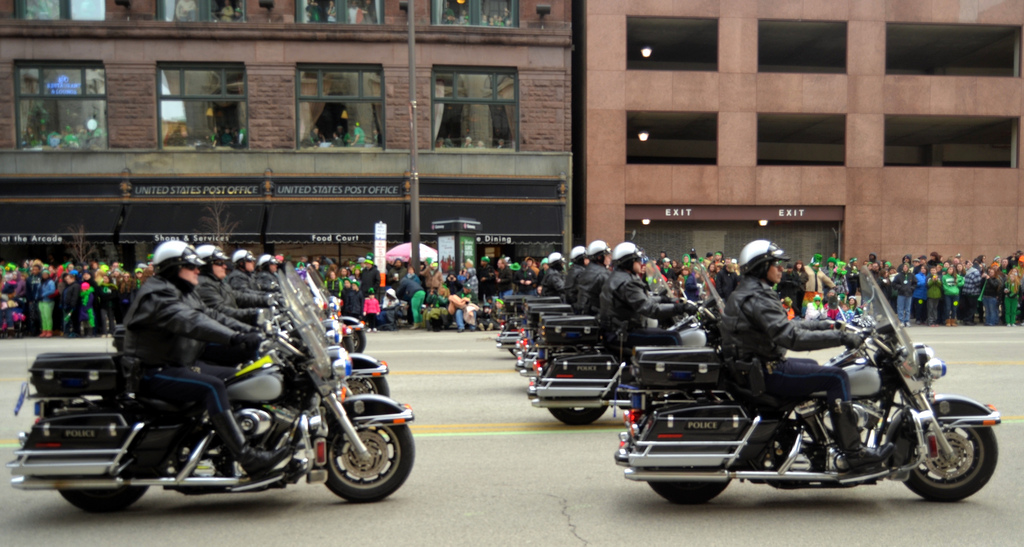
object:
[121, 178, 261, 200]
sign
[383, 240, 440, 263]
umbrella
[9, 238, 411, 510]
row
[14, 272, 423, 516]
motorcycle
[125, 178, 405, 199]
sign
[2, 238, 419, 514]
horse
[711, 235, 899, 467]
person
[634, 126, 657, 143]
light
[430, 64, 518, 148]
window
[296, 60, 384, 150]
window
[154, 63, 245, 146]
window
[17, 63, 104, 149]
window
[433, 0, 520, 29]
window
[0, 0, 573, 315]
building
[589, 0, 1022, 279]
garage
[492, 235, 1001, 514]
front row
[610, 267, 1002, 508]
motorcycle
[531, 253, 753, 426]
motorcycle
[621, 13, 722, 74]
opening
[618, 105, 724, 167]
opening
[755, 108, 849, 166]
opening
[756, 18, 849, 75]
opening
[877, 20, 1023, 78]
opening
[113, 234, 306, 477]
person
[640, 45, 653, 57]
light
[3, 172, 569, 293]
food court